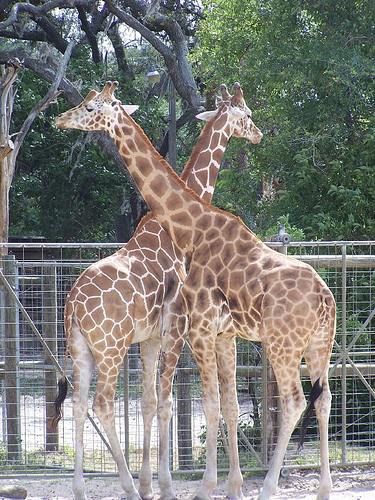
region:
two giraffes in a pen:
[28, 66, 341, 498]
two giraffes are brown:
[34, 53, 346, 498]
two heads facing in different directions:
[37, 59, 322, 213]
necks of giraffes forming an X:
[41, 72, 285, 283]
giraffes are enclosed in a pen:
[4, 72, 373, 489]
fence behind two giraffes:
[3, 219, 373, 478]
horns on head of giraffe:
[203, 76, 267, 151]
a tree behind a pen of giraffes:
[240, 5, 373, 223]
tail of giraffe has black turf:
[39, 288, 81, 438]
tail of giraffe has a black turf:
[290, 281, 343, 462]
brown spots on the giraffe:
[210, 236, 241, 291]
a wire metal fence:
[342, 374, 374, 466]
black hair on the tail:
[312, 381, 321, 398]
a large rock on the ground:
[3, 483, 32, 499]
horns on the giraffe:
[216, 82, 245, 98]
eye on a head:
[85, 102, 95, 113]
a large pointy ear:
[198, 102, 218, 121]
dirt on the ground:
[29, 482, 64, 499]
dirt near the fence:
[289, 475, 313, 498]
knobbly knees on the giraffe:
[142, 394, 178, 419]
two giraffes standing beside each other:
[36, 80, 349, 498]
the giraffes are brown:
[44, 77, 342, 494]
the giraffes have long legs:
[47, 323, 342, 494]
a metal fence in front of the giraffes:
[0, 225, 373, 476]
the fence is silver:
[1, 228, 373, 483]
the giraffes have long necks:
[49, 84, 275, 251]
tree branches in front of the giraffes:
[2, 0, 264, 179]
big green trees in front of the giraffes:
[191, 0, 374, 241]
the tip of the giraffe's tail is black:
[47, 300, 77, 436]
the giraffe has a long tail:
[294, 286, 340, 452]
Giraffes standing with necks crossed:
[48, 78, 346, 499]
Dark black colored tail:
[49, 374, 70, 431]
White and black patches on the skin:
[80, 282, 134, 332]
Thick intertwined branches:
[0, 0, 203, 115]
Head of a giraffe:
[50, 79, 122, 133]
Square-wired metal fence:
[0, 239, 373, 472]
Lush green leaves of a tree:
[259, 64, 373, 238]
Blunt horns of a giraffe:
[218, 81, 245, 104]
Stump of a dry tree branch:
[1, 137, 13, 156]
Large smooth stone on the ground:
[0, 481, 28, 499]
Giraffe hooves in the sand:
[58, 441, 334, 497]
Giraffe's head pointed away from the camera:
[191, 77, 271, 149]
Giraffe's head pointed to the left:
[47, 76, 152, 134]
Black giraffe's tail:
[42, 371, 74, 432]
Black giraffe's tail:
[298, 374, 325, 464]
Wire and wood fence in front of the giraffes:
[3, 246, 372, 466]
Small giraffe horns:
[213, 76, 249, 102]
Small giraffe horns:
[97, 73, 125, 96]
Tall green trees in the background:
[206, 11, 373, 234]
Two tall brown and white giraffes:
[41, 77, 339, 491]